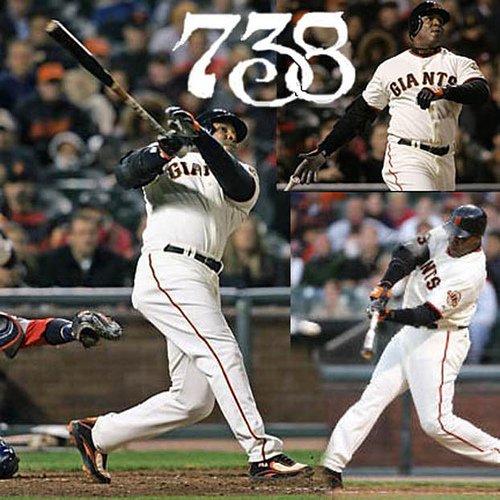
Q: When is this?
A: Daytime.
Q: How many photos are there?
A: Three.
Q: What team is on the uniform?
A: Giants.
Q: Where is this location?
A: Ball field.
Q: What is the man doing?
A: Batting.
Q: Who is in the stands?
A: Ball fans.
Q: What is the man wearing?
A: Hat.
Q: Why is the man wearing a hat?
A: For protection.